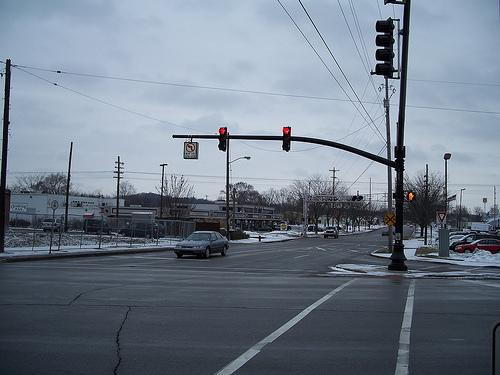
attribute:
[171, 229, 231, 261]
car — stopped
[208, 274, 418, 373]
markings — white, street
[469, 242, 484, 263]
pile — snow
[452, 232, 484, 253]
car — red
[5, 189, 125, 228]
building — small, white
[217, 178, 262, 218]
tree — tall, leafless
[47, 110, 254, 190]
cloud — large, white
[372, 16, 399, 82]
lights — four, street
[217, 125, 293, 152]
lights — street, red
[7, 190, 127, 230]
building — long, white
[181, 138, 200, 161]
sign — white, red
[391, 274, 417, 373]
stripe — long, white